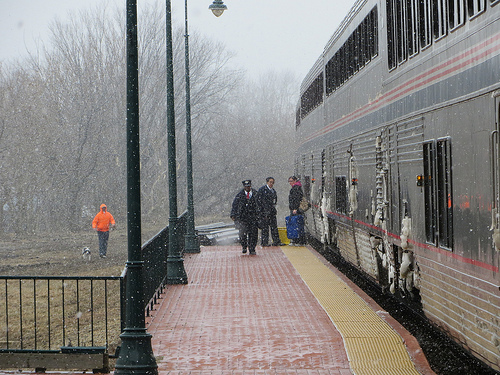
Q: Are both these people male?
A: No, they are both male and female.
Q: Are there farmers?
A: No, there are no farmers.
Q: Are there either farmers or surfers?
A: No, there are no farmers or surfers.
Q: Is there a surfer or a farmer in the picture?
A: No, there are no farmers or surfers.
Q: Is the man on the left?
A: Yes, the man is on the left of the image.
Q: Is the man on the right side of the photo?
A: No, the man is on the left of the image.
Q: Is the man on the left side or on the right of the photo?
A: The man is on the left of the image.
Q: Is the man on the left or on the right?
A: The man is on the left of the image.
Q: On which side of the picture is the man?
A: The man is on the left of the image.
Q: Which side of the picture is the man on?
A: The man is on the left of the image.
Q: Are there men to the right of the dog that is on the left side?
A: Yes, there is a man to the right of the dog.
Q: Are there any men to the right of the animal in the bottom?
A: Yes, there is a man to the right of the dog.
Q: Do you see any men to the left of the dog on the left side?
A: No, the man is to the right of the dog.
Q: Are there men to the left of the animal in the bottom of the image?
A: No, the man is to the right of the dog.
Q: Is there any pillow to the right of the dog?
A: No, there is a man to the right of the dog.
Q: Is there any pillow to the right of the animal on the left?
A: No, there is a man to the right of the dog.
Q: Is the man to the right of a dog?
A: Yes, the man is to the right of a dog.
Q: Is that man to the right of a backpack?
A: No, the man is to the right of a dog.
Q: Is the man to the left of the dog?
A: No, the man is to the right of the dog.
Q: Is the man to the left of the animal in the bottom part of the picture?
A: No, the man is to the right of the dog.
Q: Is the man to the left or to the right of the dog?
A: The man is to the right of the dog.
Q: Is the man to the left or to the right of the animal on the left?
A: The man is to the right of the dog.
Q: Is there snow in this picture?
A: Yes, there is snow.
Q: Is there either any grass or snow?
A: Yes, there is snow.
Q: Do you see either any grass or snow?
A: Yes, there is snow.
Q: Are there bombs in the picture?
A: No, there are no bombs.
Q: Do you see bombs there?
A: No, there are no bombs.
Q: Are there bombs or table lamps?
A: No, there are no bombs or table lamps.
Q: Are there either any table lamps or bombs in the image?
A: No, there are no bombs or table lamps.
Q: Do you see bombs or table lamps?
A: No, there are no bombs or table lamps.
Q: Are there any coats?
A: Yes, there is a coat.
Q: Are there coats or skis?
A: Yes, there is a coat.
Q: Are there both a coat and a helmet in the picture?
A: No, there is a coat but no helmets.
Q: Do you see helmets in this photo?
A: No, there are no helmets.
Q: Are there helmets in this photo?
A: No, there are no helmets.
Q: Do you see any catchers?
A: No, there are no catchers.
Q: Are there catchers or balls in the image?
A: No, there are no catchers or balls.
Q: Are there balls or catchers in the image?
A: No, there are no catchers or balls.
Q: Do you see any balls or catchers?
A: No, there are no catchers or balls.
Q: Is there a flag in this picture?
A: No, there are no flags.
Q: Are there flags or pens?
A: No, there are no flags or pens.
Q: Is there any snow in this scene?
A: Yes, there is snow.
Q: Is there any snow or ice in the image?
A: Yes, there is snow.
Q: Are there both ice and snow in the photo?
A: No, there is snow but no ice.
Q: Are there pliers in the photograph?
A: No, there are no pliers.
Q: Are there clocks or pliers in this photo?
A: No, there are no pliers or clocks.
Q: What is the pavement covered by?
A: The pavement is covered by the snow.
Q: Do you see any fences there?
A: Yes, there is a fence.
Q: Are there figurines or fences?
A: Yes, there is a fence.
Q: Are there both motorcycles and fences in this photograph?
A: No, there is a fence but no motorcycles.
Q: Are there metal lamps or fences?
A: Yes, there is a metal fence.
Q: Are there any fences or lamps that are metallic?
A: Yes, the fence is metallic.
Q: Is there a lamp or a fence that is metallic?
A: Yes, the fence is metallic.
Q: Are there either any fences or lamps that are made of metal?
A: Yes, the fence is made of metal.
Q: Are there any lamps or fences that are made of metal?
A: Yes, the fence is made of metal.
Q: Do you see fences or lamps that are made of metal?
A: Yes, the fence is made of metal.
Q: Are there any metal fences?
A: Yes, there is a metal fence.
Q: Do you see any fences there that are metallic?
A: Yes, there is a fence that is metallic.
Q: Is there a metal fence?
A: Yes, there is a fence that is made of metal.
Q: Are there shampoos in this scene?
A: No, there are no shampoos.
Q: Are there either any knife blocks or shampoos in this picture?
A: No, there are no shampoos or knife blocks.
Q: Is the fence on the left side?
A: Yes, the fence is on the left of the image.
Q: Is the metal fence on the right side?
A: No, the fence is on the left of the image.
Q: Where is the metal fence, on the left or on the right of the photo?
A: The fence is on the left of the image.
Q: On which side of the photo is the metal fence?
A: The fence is on the left of the image.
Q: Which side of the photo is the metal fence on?
A: The fence is on the left of the image.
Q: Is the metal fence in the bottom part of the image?
A: Yes, the fence is in the bottom of the image.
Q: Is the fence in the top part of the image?
A: No, the fence is in the bottom of the image.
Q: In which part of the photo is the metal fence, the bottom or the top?
A: The fence is in the bottom of the image.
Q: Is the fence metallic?
A: Yes, the fence is metallic.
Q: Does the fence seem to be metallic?
A: Yes, the fence is metallic.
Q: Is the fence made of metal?
A: Yes, the fence is made of metal.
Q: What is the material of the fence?
A: The fence is made of metal.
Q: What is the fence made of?
A: The fence is made of metal.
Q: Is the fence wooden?
A: No, the fence is metallic.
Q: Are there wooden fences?
A: No, there is a fence but it is metallic.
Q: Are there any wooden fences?
A: No, there is a fence but it is metallic.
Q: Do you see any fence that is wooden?
A: No, there is a fence but it is metallic.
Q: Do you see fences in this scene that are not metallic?
A: No, there is a fence but it is metallic.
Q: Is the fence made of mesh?
A: No, the fence is made of metal.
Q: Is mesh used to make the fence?
A: No, the fence is made of metal.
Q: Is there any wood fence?
A: No, there is a fence but it is made of metal.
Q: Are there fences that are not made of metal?
A: No, there is a fence but it is made of metal.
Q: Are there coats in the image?
A: Yes, there is a coat.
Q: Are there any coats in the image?
A: Yes, there is a coat.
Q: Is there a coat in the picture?
A: Yes, there is a coat.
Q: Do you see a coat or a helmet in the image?
A: Yes, there is a coat.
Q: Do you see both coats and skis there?
A: No, there is a coat but no skis.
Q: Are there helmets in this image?
A: No, there are no helmets.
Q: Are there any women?
A: Yes, there is a woman.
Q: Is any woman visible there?
A: Yes, there is a woman.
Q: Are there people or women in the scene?
A: Yes, there is a woman.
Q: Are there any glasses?
A: No, there are no glasses.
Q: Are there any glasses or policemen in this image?
A: No, there are no glasses or policemen.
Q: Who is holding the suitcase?
A: The woman is holding the suitcase.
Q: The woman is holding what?
A: The woman is holding the suitcase.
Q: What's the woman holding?
A: The woman is holding the suitcase.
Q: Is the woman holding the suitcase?
A: Yes, the woman is holding the suitcase.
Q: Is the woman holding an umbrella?
A: No, the woman is holding the suitcase.